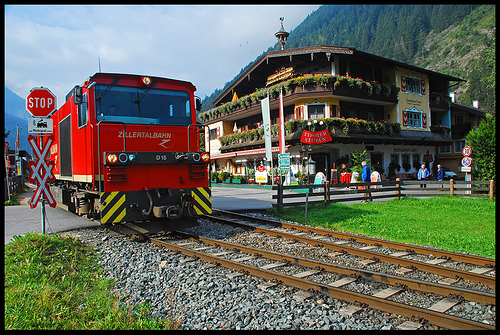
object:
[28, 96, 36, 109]
letters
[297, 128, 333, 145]
banner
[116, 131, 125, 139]
letters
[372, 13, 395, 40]
leaf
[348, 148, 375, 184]
plant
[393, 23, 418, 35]
leaf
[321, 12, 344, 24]
leaf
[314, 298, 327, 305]
gravel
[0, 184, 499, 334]
ground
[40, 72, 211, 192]
car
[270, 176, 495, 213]
fence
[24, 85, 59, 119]
sign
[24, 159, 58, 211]
crossing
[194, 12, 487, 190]
building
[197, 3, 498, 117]
hill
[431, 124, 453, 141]
plants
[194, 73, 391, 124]
building railing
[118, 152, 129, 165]
lights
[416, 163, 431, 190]
people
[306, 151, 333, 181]
entrance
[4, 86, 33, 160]
sections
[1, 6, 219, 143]
distance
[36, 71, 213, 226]
train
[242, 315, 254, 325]
rocks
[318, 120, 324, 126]
flowers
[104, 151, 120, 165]
light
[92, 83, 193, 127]
train windshield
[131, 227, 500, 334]
tracks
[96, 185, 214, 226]
bumper